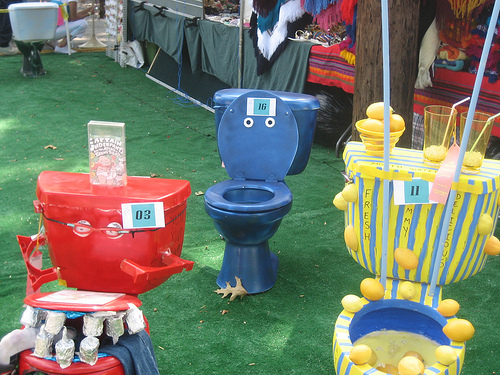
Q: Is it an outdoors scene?
A: Yes, it is outdoors.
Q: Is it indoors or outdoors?
A: It is outdoors.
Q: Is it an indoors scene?
A: No, it is outdoors.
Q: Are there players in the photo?
A: No, there are no players.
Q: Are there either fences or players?
A: No, there are no players or fences.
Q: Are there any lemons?
A: Yes, there are lemons.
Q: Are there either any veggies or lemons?
A: Yes, there are lemons.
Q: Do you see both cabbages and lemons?
A: No, there are lemons but no cabbages.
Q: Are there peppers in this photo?
A: No, there are no peppers.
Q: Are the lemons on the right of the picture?
A: Yes, the lemons are on the right of the image.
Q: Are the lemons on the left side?
A: No, the lemons are on the right of the image.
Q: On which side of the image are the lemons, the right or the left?
A: The lemons are on the right of the image.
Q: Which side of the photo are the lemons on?
A: The lemons are on the right of the image.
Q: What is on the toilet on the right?
A: The lemons are on the toilet.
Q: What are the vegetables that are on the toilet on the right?
A: The vegetables are lemons.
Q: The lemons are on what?
A: The lemons are on the toilet.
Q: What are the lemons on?
A: The lemons are on the toilet.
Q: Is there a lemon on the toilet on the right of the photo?
A: Yes, there are lemons on the toilet.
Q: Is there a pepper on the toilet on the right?
A: No, there are lemons on the toilet.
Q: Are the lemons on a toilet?
A: Yes, the lemons are on a toilet.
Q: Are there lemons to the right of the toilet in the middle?
A: Yes, there are lemons to the right of the toilet.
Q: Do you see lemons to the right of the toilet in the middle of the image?
A: Yes, there are lemons to the right of the toilet.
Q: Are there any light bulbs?
A: No, there are no light bulbs.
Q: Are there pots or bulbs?
A: No, there are no bulbs or pots.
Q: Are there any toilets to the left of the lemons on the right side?
A: Yes, there is a toilet to the left of the lemons.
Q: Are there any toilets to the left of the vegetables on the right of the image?
A: Yes, there is a toilet to the left of the lemons.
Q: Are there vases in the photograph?
A: No, there are no vases.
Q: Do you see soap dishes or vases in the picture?
A: No, there are no vases or soap dishes.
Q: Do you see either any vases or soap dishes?
A: No, there are no vases or soap dishes.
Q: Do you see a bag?
A: No, there are no bags.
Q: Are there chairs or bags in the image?
A: No, there are no bags or chairs.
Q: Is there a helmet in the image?
A: No, there are no helmets.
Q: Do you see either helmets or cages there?
A: No, there are no helmets or cages.